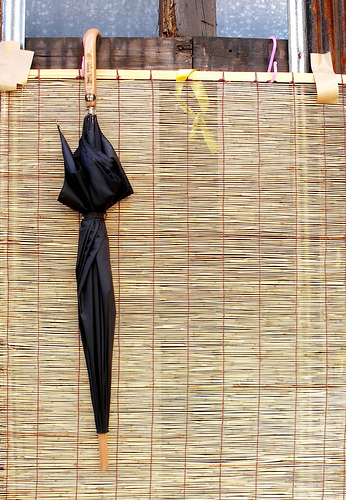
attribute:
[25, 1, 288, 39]
glass — white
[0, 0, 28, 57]
siding — metal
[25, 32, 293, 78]
board — long, brown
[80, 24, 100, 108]
hook — pink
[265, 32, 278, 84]
hook — pink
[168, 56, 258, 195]
ribbon — yellow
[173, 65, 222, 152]
ribbon — yellow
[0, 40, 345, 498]
basket — wooden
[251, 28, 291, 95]
hook — pink S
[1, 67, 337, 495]
blind — long, brown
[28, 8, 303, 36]
window — dirty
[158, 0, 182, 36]
rotted wood — rotten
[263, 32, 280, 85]
hook — plastic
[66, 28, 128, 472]
umbrella — black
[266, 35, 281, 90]
hook — pink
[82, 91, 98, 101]
sticker — black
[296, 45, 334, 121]
strip — packed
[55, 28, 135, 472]
umbrella — black, brown, wood grain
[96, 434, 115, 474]
tips — light brown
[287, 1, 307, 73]
siding — metal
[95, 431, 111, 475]
tip — light brown